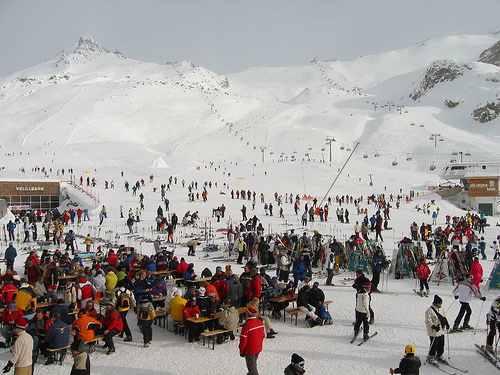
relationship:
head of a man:
[245, 304, 259, 314] [236, 305, 270, 373]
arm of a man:
[228, 320, 255, 352] [224, 305, 276, 361]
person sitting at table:
[188, 298, 200, 317] [192, 314, 261, 327]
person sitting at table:
[201, 291, 221, 307] [271, 288, 317, 313]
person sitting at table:
[75, 309, 97, 327] [144, 291, 169, 313]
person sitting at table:
[297, 279, 309, 301] [35, 294, 61, 314]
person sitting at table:
[267, 279, 285, 293] [149, 264, 183, 282]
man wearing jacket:
[74, 308, 102, 355] [69, 314, 100, 341]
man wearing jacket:
[237, 293, 270, 363] [235, 313, 278, 353]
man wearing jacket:
[352, 280, 373, 343] [354, 281, 369, 340]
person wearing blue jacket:
[7, 220, 17, 241] [6, 224, 13, 230]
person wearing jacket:
[42, 312, 62, 356] [36, 311, 76, 358]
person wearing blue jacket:
[227, 273, 233, 285] [223, 268, 238, 289]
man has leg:
[353, 280, 370, 337] [353, 313, 359, 338]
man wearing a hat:
[237, 308, 265, 375] [244, 304, 260, 319]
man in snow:
[352, 280, 373, 343] [7, 44, 496, 374]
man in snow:
[237, 308, 265, 375] [7, 44, 496, 374]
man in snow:
[423, 291, 449, 364] [7, 44, 496, 374]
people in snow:
[395, 345, 420, 373] [7, 44, 496, 374]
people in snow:
[453, 267, 480, 334] [7, 44, 496, 374]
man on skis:
[352, 280, 373, 343] [348, 322, 385, 348]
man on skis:
[423, 287, 450, 365] [431, 344, 468, 373]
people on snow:
[386, 237, 444, 297] [7, 44, 496, 374]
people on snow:
[442, 228, 489, 290] [7, 44, 496, 374]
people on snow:
[74, 274, 133, 347] [7, 44, 496, 374]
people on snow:
[168, 278, 237, 346] [7, 44, 496, 374]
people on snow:
[146, 197, 183, 245] [7, 44, 496, 374]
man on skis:
[352, 280, 373, 343] [349, 324, 378, 345]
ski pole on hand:
[421, 332, 441, 362] [429, 322, 444, 336]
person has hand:
[421, 294, 463, 360] [429, 322, 444, 336]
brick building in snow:
[2, 176, 62, 222] [59, 181, 91, 221]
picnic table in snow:
[186, 307, 241, 346] [7, 44, 496, 374]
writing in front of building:
[14, 185, 46, 192] [0, 180, 62, 217]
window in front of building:
[38, 191, 53, 203] [1, 152, 74, 216]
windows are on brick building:
[16, 186, 67, 211] [0, 172, 62, 222]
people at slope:
[412, 255, 433, 298] [78, 49, 459, 169]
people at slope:
[2, 161, 496, 368] [7, 36, 498, 219]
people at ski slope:
[6, 132, 498, 369] [1, 34, 498, 374]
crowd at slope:
[187, 205, 352, 282] [2, 206, 493, 371]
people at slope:
[2, 161, 496, 368] [5, 186, 493, 374]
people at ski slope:
[2, 161, 496, 368] [3, 62, 495, 214]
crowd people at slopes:
[1, 242, 332, 361] [0, 36, 499, 233]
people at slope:
[2, 161, 496, 368] [9, 90, 498, 373]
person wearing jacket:
[167, 286, 188, 329] [167, 295, 187, 322]